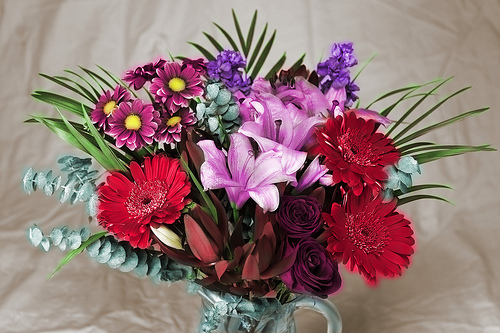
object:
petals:
[159, 59, 199, 77]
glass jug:
[187, 280, 341, 330]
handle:
[291, 295, 343, 333]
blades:
[363, 75, 496, 209]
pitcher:
[185, 280, 340, 330]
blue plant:
[29, 224, 186, 285]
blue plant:
[22, 152, 102, 217]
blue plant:
[191, 82, 246, 145]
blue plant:
[381, 157, 421, 199]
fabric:
[0, 3, 495, 331]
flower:
[97, 56, 420, 295]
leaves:
[23, 64, 142, 181]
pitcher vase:
[186, 281, 343, 331]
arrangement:
[21, 9, 498, 300]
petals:
[288, 241, 304, 281]